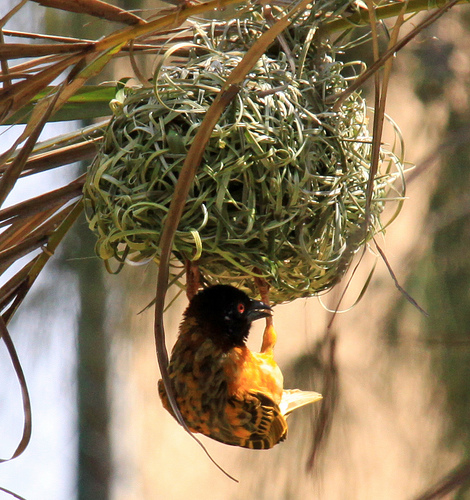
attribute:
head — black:
[178, 285, 273, 355]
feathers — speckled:
[170, 357, 226, 418]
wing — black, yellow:
[192, 372, 289, 448]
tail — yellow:
[279, 386, 325, 420]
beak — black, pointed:
[245, 296, 272, 323]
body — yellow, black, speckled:
[158, 319, 291, 447]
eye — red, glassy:
[233, 302, 244, 315]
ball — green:
[76, 27, 419, 319]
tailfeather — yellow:
[281, 384, 322, 421]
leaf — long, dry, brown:
[156, 0, 321, 485]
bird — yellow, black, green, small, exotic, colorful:
[158, 260, 325, 453]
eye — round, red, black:
[231, 301, 246, 316]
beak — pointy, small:
[247, 301, 270, 321]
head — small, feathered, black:
[182, 278, 274, 346]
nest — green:
[86, 8, 409, 305]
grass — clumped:
[88, 15, 405, 305]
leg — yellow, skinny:
[247, 248, 279, 353]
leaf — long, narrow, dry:
[153, 12, 296, 485]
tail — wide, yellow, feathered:
[279, 384, 320, 414]